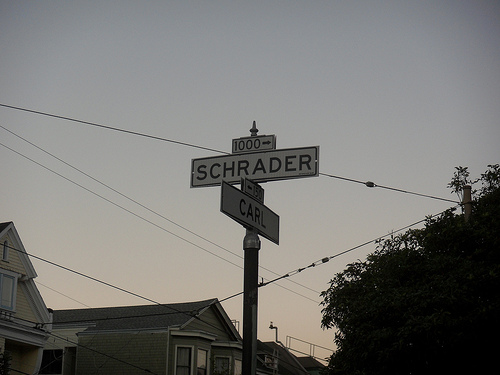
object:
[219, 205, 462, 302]
pole wire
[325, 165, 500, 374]
trees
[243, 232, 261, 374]
street pole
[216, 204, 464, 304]
telephone wires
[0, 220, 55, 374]
houses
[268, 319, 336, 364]
searcher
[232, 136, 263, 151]
numbers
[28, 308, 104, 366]
houses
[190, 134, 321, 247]
schrader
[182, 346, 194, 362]
windows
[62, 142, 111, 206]
these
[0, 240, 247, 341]
wires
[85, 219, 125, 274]
color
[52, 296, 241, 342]
roof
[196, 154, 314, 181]
street sign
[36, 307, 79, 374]
intersection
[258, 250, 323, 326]
sunset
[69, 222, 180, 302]
behind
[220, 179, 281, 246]
street sign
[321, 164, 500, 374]
hedge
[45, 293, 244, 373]
house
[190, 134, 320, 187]
street sign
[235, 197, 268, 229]
text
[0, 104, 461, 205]
power lines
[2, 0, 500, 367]
sky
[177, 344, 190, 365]
curtains